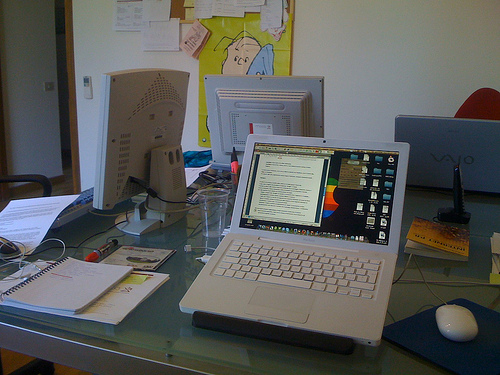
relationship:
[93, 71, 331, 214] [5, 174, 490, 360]
monitors on table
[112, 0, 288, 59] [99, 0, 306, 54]
bulletin board on bulletin board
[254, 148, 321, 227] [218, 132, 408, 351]
document on laptop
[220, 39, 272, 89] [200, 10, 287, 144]
linus on poster